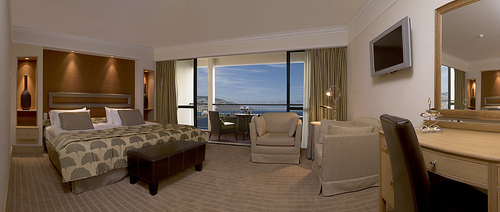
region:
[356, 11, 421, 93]
television on a wall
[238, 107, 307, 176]
chair on the floor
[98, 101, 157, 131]
pillows on a bed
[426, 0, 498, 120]
mirror on the wall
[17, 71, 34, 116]
vase on a shelf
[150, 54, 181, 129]
tan curtains on a window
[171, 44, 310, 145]
window in a room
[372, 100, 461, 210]
chair near a desk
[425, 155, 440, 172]
handle on a desk drawer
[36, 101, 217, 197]
bed in a room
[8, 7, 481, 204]
A picture of a bedroom.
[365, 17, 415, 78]
Tv mounted on the wall.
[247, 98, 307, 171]
A white chair with pillows.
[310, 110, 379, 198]
A white couch with pillows.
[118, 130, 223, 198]
A bench at the foot of the bed.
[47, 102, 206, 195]
A large bed.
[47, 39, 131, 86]
Ceiling lights turned on.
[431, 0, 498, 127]
A large square mirror.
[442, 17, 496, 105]
The reflection of the room in mirror.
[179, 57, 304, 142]
Sliding glass doors to the balcony.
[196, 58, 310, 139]
View to outside balcony.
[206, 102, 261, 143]
Dining set on balcony.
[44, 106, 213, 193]
King size bed in bedroom.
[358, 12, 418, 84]
Flat screen television mounted on wall.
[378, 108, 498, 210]
Vanity with chair and mirror.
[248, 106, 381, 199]
Chair and sofa near balcony opening.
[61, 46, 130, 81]
Lights mounted above the bed.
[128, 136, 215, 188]
Brown wood chest at foot of bed.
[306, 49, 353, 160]
Drapes to balcony's glass sliding door.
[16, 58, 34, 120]
Vase sitting on shelf highlighted with light.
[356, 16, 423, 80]
flat screened television on a wall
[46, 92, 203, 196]
large, neatly made bed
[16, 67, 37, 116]
dark, decorative vase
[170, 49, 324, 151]
large, open, sliding doors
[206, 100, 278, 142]
table and chairs on a balcony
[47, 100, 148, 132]
many pillows on a bed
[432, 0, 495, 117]
large mirror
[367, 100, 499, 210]
wooden desk with a chair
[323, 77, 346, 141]
floor lamp without a shade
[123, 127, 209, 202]
wooden bench at the end of a bed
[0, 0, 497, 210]
modern bedroom on an upper floor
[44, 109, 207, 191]
king size bed in a master bedroom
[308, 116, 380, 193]
beige sofa against the wall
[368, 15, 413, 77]
flat tv monitor mounted on the wall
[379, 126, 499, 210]
wooden desk against the wall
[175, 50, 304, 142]
balcony terrace behind the lounge chair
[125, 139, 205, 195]
dark wood bedside bench at the foot of the bed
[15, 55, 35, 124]
recessed shelf on each side of the bed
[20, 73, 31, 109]
decorative art in recessed shelf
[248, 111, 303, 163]
beige chair next to the sofa